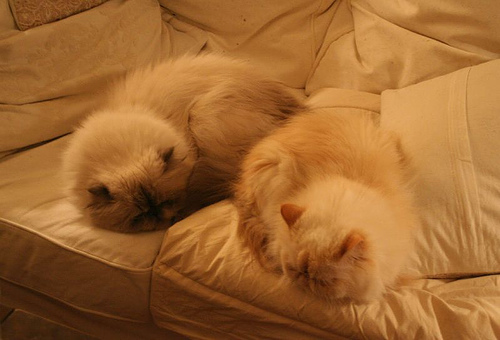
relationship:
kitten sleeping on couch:
[222, 96, 428, 307] [7, 5, 494, 331]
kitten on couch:
[222, 96, 428, 307] [7, 5, 494, 331]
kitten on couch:
[60, 43, 309, 235] [7, 5, 494, 331]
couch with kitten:
[7, 5, 494, 331] [60, 43, 309, 235]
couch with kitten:
[7, 5, 494, 331] [222, 96, 428, 307]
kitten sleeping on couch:
[49, 36, 287, 226] [0, 0, 495, 337]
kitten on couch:
[49, 36, 287, 226] [0, 0, 495, 337]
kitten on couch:
[222, 96, 428, 307] [0, 0, 495, 337]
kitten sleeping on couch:
[222, 96, 428, 307] [0, 0, 495, 337]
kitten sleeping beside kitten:
[222, 96, 428, 307] [60, 43, 309, 235]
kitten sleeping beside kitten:
[60, 43, 309, 235] [222, 96, 428, 307]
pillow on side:
[375, 50, 500, 288] [383, 2, 498, 334]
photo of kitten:
[8, 2, 498, 331] [49, 36, 287, 226]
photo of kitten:
[8, 2, 498, 331] [222, 96, 428, 307]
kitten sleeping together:
[222, 96, 428, 307] [51, 50, 431, 298]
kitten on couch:
[49, 36, 287, 226] [7, 5, 494, 331]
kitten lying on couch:
[49, 36, 287, 226] [7, 5, 494, 331]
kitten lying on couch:
[222, 96, 428, 307] [7, 5, 494, 331]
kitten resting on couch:
[49, 36, 287, 226] [0, 0, 495, 337]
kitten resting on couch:
[222, 96, 428, 307] [0, 0, 495, 337]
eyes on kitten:
[128, 195, 178, 223] [49, 36, 287, 226]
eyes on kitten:
[286, 259, 341, 288] [222, 96, 428, 307]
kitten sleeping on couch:
[60, 43, 309, 235] [7, 5, 494, 331]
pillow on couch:
[375, 50, 500, 288] [7, 5, 494, 331]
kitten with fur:
[222, 96, 428, 307] [250, 124, 399, 286]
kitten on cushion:
[222, 96, 428, 307] [155, 197, 500, 336]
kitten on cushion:
[60, 43, 309, 235] [3, 126, 197, 310]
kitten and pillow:
[60, 43, 309, 235] [375, 50, 500, 288]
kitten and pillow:
[222, 96, 428, 307] [375, 50, 500, 288]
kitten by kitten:
[60, 43, 309, 235] [222, 96, 428, 307]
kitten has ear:
[60, 43, 309, 235] [82, 179, 110, 208]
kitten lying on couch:
[60, 43, 309, 235] [7, 5, 494, 331]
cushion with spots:
[155, 197, 500, 336] [418, 277, 491, 320]